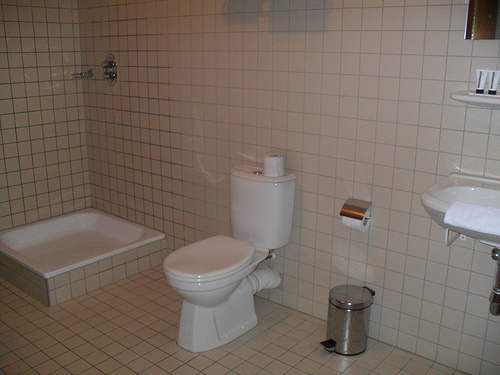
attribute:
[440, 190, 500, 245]
towel — white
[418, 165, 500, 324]
sink — white, closed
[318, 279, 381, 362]
trash can — metal, round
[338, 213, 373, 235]
toilet paper — white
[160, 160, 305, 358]
toilet — white, clean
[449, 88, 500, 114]
shelf — white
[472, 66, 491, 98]
bottle — small, black, white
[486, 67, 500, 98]
bottle — small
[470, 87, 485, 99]
cap — black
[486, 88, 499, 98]
cap — black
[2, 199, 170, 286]
shower base — white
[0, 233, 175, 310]
tiles — beige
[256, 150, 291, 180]
toilet paper — fresh, new